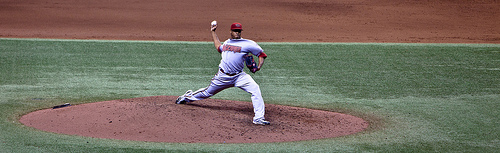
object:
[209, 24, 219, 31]
hand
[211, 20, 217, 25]
ball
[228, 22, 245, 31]
cap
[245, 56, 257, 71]
glove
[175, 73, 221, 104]
leg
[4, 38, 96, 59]
pitch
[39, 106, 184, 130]
soil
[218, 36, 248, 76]
jersey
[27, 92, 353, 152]
ground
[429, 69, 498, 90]
grass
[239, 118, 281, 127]
feet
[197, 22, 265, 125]
man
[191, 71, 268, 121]
pants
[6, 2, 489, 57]
court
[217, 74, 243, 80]
belt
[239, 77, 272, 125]
legs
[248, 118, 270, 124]
shoes